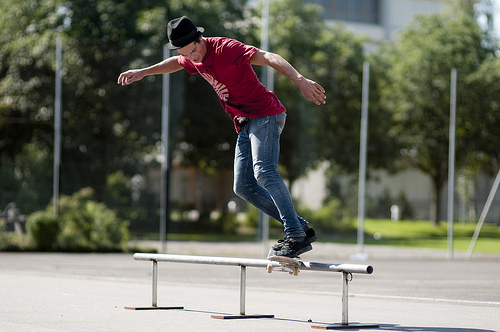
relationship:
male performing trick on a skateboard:
[117, 16, 326, 259] [263, 250, 303, 274]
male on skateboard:
[143, 8, 344, 223] [258, 252, 320, 279]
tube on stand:
[130, 237, 398, 291] [332, 266, 362, 322]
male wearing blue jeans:
[117, 16, 326, 259] [218, 110, 327, 237]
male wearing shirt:
[117, 16, 326, 259] [199, 50, 282, 140]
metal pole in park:
[327, 47, 415, 225] [283, 28, 441, 245]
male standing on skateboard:
[117, 16, 326, 259] [265, 248, 302, 277]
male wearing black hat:
[117, 16, 326, 259] [165, 16, 205, 51]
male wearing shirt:
[117, 16, 326, 259] [156, 25, 294, 160]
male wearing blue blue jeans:
[117, 16, 326, 259] [232, 110, 310, 238]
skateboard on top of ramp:
[265, 248, 302, 277] [131, 251, 373, 274]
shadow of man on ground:
[311, 300, 492, 330] [0, 201, 488, 329]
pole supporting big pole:
[131, 250, 372, 274] [339, 267, 352, 324]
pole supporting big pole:
[238, 263, 246, 314] [150, 260, 160, 305]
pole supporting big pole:
[464, 166, 499, 258] [446, 67, 460, 255]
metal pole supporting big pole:
[355, 61, 368, 257] [256, 3, 274, 253]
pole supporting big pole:
[156, 41, 168, 254] [52, 34, 59, 194]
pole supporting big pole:
[239, 265, 246, 314] [131, 250, 372, 274]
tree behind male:
[0, 0, 500, 233] [117, 16, 326, 259]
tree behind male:
[68, 0, 267, 223] [117, 16, 326, 259]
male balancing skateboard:
[117, 16, 326, 259] [265, 248, 302, 277]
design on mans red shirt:
[203, 73, 235, 105] [117, 17, 343, 256]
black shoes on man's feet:
[251, 212, 330, 248] [278, 234, 315, 266]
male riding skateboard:
[117, 16, 326, 259] [262, 252, 312, 274]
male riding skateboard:
[117, 16, 326, 259] [250, 238, 311, 292]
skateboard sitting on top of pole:
[262, 241, 305, 278] [211, 249, 250, 273]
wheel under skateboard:
[265, 263, 273, 273] [266, 250, 300, 274]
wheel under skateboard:
[288, 267, 298, 278] [266, 250, 300, 274]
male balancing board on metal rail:
[117, 16, 326, 259] [123, 252, 373, 329]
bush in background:
[25, 184, 130, 253] [4, 1, 484, 246]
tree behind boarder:
[0, 0, 500, 233] [108, 9, 328, 268]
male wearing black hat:
[117, 16, 326, 259] [157, 9, 207, 51]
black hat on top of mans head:
[165, 16, 205, 51] [165, 14, 207, 61]